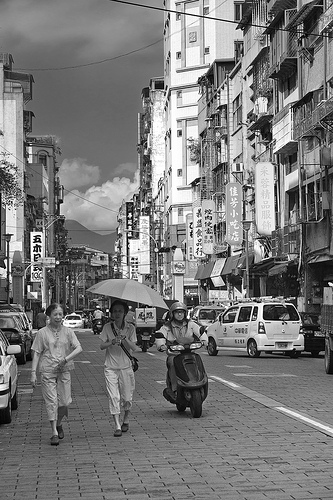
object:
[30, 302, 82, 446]
woman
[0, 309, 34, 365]
vehicle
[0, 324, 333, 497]
road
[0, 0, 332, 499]
scene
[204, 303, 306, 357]
car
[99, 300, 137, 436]
woman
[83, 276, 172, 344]
umbrella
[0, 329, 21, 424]
vehicle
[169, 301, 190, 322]
helmet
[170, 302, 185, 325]
head